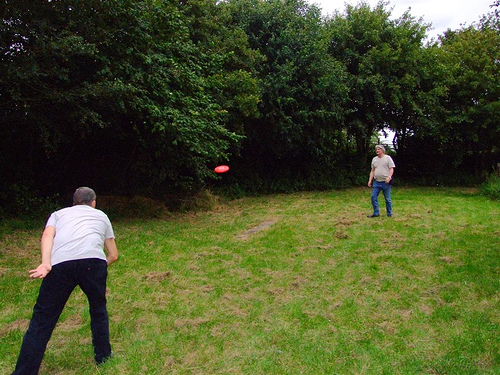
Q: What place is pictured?
A: It is a yard.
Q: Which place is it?
A: It is a yard.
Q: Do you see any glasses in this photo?
A: No, there are no glasses.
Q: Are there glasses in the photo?
A: No, there are no glasses.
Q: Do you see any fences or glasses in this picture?
A: No, there are no glasses or fences.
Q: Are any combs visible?
A: No, there are no combs.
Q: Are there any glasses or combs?
A: No, there are no combs or glasses.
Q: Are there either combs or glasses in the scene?
A: No, there are no combs or glasses.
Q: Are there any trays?
A: No, there are no trays.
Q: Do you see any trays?
A: No, there are no trays.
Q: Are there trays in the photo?
A: No, there are no trays.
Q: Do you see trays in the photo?
A: No, there are no trays.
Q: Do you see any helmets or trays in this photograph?
A: No, there are no trays or helmets.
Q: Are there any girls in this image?
A: No, there are no girls.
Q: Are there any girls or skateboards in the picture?
A: No, there are no girls or skateboards.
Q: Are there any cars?
A: No, there are no cars.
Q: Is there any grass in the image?
A: Yes, there is grass.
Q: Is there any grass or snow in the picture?
A: Yes, there is grass.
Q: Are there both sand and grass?
A: No, there is grass but no sand.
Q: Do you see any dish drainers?
A: No, there are no dish drainers.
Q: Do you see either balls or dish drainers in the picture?
A: No, there are no dish drainers or balls.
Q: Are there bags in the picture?
A: No, there are no bags.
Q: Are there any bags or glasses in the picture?
A: No, there are no bags or glasses.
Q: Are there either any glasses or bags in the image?
A: No, there are no bags or glasses.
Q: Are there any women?
A: No, there are no women.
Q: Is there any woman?
A: No, there are no women.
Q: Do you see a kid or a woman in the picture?
A: No, there are no women or children.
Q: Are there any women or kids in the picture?
A: No, there are no women or kids.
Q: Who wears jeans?
A: The man wears jeans.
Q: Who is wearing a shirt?
A: The man is wearing a shirt.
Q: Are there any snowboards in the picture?
A: No, there are no snowboards.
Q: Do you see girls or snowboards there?
A: No, there are no snowboards or girls.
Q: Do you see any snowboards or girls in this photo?
A: No, there are no snowboards or girls.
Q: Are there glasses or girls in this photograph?
A: No, there are no glasses or girls.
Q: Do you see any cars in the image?
A: No, there are no cars.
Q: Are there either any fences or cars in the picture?
A: No, there are no cars or fences.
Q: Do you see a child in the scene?
A: No, there are no children.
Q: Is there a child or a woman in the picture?
A: No, there are no children or women.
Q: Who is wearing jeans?
A: The man is wearing jeans.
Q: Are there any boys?
A: No, there are no boys.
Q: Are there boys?
A: No, there are no boys.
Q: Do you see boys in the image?
A: No, there are no boys.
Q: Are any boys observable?
A: No, there are no boys.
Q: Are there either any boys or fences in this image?
A: No, there are no boys or fences.